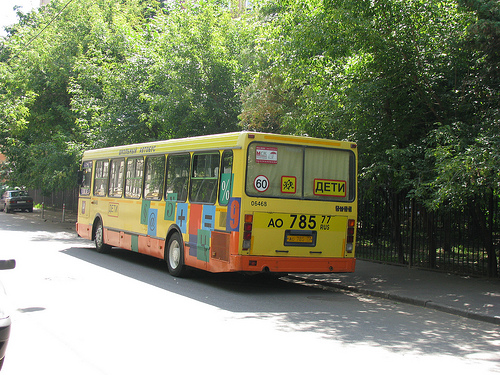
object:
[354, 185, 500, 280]
fence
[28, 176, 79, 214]
fence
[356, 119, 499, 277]
trees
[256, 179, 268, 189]
60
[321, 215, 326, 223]
number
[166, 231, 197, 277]
tire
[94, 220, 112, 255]
tire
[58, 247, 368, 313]
shadow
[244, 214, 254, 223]
lights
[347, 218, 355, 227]
lights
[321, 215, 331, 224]
number 77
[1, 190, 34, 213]
car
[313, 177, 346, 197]
sign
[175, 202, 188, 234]
sign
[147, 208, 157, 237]
signs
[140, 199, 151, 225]
signs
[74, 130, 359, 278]
bus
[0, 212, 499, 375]
road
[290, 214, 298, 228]
number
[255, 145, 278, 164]
sign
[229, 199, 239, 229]
9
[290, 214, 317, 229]
785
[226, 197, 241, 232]
blue background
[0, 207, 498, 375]
ground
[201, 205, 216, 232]
equal sign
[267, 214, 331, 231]
ao78577rus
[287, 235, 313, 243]
license plate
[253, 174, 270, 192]
sign